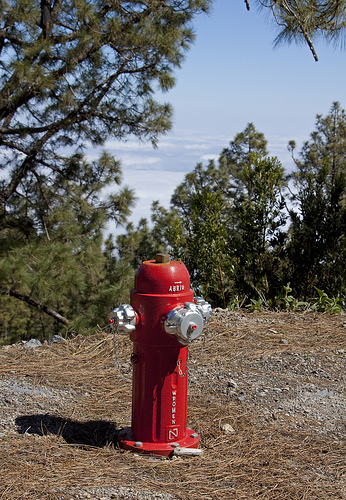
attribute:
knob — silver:
[187, 323, 200, 331]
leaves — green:
[216, 261, 240, 276]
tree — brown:
[172, 122, 298, 302]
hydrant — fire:
[137, 255, 212, 417]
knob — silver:
[166, 301, 204, 339]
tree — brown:
[0, 7, 127, 258]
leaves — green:
[250, 175, 260, 182]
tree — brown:
[211, 115, 283, 302]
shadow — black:
[17, 410, 128, 452]